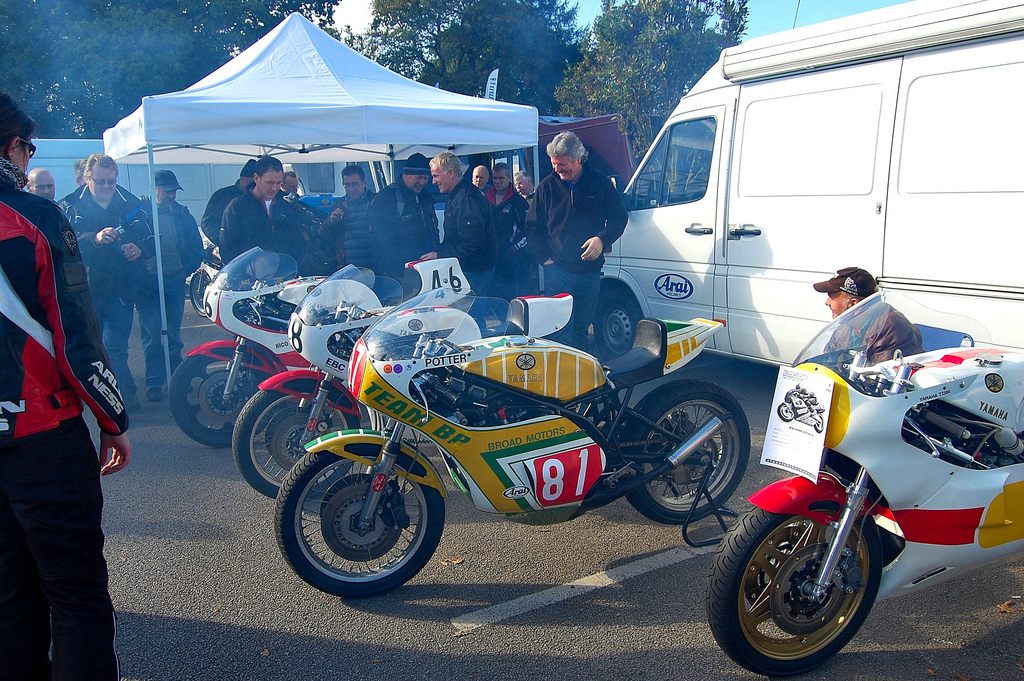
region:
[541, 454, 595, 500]
numbers in white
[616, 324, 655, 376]
the seat is black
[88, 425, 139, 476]
a persons hand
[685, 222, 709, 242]
handle on the door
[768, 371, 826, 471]
a white paper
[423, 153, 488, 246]
a man standing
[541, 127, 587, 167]
Man has gray hair on head.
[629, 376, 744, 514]
Back wheel on bike is black.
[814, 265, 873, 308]
Person wearing baseball cap on head.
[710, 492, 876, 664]
Front wheel on bike is black.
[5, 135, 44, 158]
Glasses on person's face.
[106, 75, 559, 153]
White top on tent over people.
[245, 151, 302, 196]
Person has dark hair on head.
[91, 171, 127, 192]
Sunglasses on man's face.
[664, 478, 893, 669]
the wheel is black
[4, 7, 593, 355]
smoke is blowing around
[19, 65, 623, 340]
men are standing around looking at the bikes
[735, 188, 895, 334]
the man is wearing a baseball cap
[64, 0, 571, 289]
the canopy is white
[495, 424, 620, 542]
the numbers are white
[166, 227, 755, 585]
Bikes lined up beside each other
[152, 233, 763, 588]
Three bikes along side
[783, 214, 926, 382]
Man kneeling beside white van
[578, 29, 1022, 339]
White van parked parallel to bikes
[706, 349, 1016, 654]
Bike sitting off to the right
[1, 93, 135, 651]
Guy in red and black jacket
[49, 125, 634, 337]
People standing underneath canopy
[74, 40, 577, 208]
White canopy sheltering people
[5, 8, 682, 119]
Trees beyond the canopy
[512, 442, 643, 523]
Number 81 on bike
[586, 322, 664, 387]
the seat of a motor bike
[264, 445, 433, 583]
the front wheel of a motor bike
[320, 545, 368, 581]
the spokes of a wheel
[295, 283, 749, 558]
a yellow colored motor bike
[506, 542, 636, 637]
a white stripe on the ground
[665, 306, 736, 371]
the tail of a motor bike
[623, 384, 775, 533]
the back wheel of a motor bike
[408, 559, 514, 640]
the shadow of a motor bike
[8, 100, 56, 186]
the head of a person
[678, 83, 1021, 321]
The van is white.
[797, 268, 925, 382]
A person sitting by the van.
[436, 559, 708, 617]
White line in the road.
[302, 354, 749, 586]
The motorcycle is yellow and green.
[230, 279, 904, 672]
Motorcycles parked by the white van.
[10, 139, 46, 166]
The person is wearing glasses.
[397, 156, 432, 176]
The man is wearing a cap.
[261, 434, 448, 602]
The front wheel of the bike.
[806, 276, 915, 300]
The man is wearing a black cap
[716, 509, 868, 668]
the wheel has a gold rim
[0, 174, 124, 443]
the jacket is black, red and white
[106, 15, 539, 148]
the top of the canopy is white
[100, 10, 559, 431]
White cloth top tent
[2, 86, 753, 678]
Group of people looking at motorcycles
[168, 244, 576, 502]
Two red and white motorcycles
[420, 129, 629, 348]
Two men with light colored hair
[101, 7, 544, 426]
Group of men standing under tent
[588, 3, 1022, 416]
White van with folding side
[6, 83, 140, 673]
Person wearing jacket and scarf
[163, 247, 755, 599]
Three motorcycles standing in a row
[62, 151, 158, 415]
Man wearing sunglasses